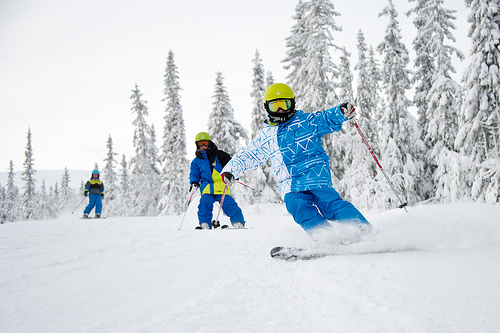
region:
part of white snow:
[160, 252, 291, 297]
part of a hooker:
[365, 154, 410, 207]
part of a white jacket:
[288, 137, 321, 195]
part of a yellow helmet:
[258, 76, 292, 100]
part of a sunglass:
[264, 98, 287, 110]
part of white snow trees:
[376, 54, 463, 167]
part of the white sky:
[18, 46, 93, 128]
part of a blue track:
[93, 199, 103, 209]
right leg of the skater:
[286, 197, 314, 219]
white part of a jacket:
[261, 149, 286, 183]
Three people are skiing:
[37, 60, 458, 290]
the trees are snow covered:
[5, 7, 495, 223]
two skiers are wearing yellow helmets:
[160, 65, 435, 272]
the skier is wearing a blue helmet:
[60, 150, 130, 227]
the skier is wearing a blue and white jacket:
[195, 75, 405, 262]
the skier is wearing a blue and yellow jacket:
[160, 120, 267, 255]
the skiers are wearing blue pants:
[57, 71, 437, 282]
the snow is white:
[5, 168, 498, 328]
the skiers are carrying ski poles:
[48, 74, 457, 276]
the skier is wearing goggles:
[206, 67, 406, 272]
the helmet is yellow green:
[259, 75, 314, 101]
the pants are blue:
[274, 182, 359, 249]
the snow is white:
[120, 257, 213, 322]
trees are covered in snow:
[261, 25, 427, 112]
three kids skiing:
[37, 89, 383, 319]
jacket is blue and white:
[217, 118, 363, 224]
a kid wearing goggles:
[262, 87, 304, 129]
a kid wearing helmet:
[171, 129, 236, 174]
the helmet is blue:
[87, 165, 99, 178]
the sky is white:
[42, 72, 109, 113]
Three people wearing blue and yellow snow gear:
[76, 70, 368, 233]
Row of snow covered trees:
[100, 4, 498, 78]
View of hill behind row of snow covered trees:
[4, 148, 79, 213]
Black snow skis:
[270, 220, 428, 272]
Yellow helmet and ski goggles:
[250, 70, 316, 137]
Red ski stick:
[341, 96, 406, 221]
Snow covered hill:
[22, 235, 173, 305]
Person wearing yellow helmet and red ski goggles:
[185, 125, 221, 161]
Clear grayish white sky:
[12, 52, 122, 109]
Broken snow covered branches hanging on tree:
[467, 115, 497, 165]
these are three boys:
[51, 86, 345, 254]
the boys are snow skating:
[55, 78, 354, 223]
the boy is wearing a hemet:
[271, 86, 286, 98]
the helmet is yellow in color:
[268, 85, 290, 95]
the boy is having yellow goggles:
[271, 100, 288, 110]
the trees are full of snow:
[287, 0, 497, 65]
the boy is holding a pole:
[363, 115, 409, 220]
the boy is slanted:
[229, 90, 343, 262]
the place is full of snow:
[33, 244, 250, 331]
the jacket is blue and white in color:
[271, 122, 309, 186]